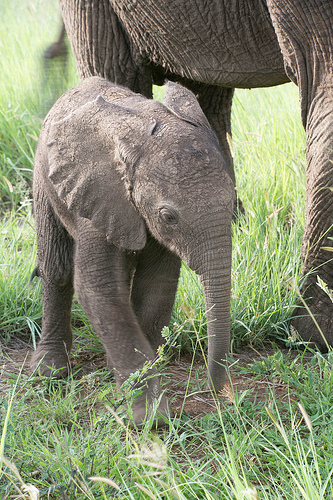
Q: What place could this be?
A: It is a field.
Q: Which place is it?
A: It is a field.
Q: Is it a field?
A: Yes, it is a field.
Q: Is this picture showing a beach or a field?
A: It is showing a field.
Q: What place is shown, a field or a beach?
A: It is a field.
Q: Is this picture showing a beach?
A: No, the picture is showing a field.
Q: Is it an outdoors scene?
A: Yes, it is outdoors.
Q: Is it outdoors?
A: Yes, it is outdoors.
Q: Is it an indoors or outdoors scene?
A: It is outdoors.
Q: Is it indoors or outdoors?
A: It is outdoors.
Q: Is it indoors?
A: No, it is outdoors.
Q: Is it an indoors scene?
A: No, it is outdoors.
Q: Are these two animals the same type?
A: Yes, all the animals are elephants.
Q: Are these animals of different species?
A: No, all the animals are elephants.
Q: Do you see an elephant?
A: Yes, there is an elephant.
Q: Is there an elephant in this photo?
A: Yes, there is an elephant.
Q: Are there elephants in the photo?
A: Yes, there is an elephant.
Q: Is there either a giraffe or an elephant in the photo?
A: Yes, there is an elephant.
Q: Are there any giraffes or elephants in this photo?
A: Yes, there is an elephant.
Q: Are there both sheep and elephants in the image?
A: No, there is an elephant but no sheep.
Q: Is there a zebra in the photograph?
A: No, there are no zebras.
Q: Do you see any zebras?
A: No, there are no zebras.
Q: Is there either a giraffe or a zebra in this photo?
A: No, there are no zebras or giraffes.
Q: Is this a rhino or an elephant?
A: This is an elephant.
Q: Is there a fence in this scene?
A: No, there are no fences.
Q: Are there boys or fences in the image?
A: No, there are no fences or boys.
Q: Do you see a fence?
A: No, there are no fences.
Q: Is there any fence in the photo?
A: No, there are no fences.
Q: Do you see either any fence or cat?
A: No, there are no fences or cats.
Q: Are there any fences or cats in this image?
A: No, there are no fences or cats.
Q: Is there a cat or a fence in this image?
A: No, there are no fences or cats.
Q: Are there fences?
A: No, there are no fences.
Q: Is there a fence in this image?
A: No, there are no fences.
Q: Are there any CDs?
A: No, there are no cds.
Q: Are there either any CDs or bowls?
A: No, there are no CDs or bowls.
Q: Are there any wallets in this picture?
A: No, there are no wallets.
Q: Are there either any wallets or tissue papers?
A: No, there are no wallets or tissue papers.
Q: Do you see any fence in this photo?
A: No, there are no fences.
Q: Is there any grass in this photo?
A: Yes, there is grass.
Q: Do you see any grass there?
A: Yes, there is grass.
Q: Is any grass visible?
A: Yes, there is grass.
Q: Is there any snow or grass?
A: Yes, there is grass.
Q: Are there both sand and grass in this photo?
A: No, there is grass but no sand.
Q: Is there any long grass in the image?
A: Yes, there is long grass.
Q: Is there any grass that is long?
A: Yes, there is grass that is long.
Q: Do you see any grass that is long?
A: Yes, there is grass that is long.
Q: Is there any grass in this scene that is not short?
A: Yes, there is long grass.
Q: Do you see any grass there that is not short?
A: Yes, there is long grass.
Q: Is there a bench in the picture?
A: No, there are no benches.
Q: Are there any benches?
A: No, there are no benches.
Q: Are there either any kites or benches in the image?
A: No, there are no benches or kites.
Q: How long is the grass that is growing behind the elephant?
A: The grass is long.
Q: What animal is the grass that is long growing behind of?
A: The grass is growing behind the elephant.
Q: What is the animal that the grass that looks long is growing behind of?
A: The animal is an elephant.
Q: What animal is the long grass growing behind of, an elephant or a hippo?
A: The grass is growing behind an elephant.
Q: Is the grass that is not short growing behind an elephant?
A: Yes, the grass is growing behind an elephant.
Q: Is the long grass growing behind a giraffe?
A: No, the grass is growing behind an elephant.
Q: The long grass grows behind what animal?
A: The grass grows behind the elephant.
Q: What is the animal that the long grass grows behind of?
A: The animal is an elephant.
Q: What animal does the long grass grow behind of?
A: The grass grows behind the elephant.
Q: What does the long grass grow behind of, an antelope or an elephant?
A: The grass grows behind an elephant.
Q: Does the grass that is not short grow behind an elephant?
A: Yes, the grass grows behind an elephant.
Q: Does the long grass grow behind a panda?
A: No, the grass grows behind an elephant.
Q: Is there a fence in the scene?
A: No, there are no fences.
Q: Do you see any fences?
A: No, there are no fences.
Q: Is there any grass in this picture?
A: Yes, there is grass.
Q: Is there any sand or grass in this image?
A: Yes, there is grass.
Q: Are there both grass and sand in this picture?
A: No, there is grass but no sand.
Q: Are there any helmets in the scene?
A: No, there are no helmets.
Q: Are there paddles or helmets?
A: No, there are no helmets or paddles.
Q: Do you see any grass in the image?
A: Yes, there is grass.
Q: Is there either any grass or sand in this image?
A: Yes, there is grass.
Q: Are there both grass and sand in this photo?
A: No, there is grass but no sand.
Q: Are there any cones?
A: No, there are no cones.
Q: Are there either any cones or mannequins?
A: No, there are no cones or mannequins.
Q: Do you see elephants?
A: Yes, there is an elephant.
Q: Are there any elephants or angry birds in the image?
A: Yes, there is an elephant.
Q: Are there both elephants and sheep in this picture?
A: No, there is an elephant but no sheep.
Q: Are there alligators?
A: No, there are no alligators.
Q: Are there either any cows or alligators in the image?
A: No, there are no alligators or cows.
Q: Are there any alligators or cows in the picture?
A: No, there are no alligators or cows.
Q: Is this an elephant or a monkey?
A: This is an elephant.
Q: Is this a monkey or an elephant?
A: This is an elephant.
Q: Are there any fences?
A: No, there are no fences.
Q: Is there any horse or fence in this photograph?
A: No, there are no fences or horses.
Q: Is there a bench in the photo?
A: No, there are no benches.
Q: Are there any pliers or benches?
A: No, there are no benches or pliers.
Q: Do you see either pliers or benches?
A: No, there are no benches or pliers.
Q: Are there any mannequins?
A: No, there are no mannequins.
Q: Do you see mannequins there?
A: No, there are no mannequins.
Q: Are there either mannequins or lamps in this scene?
A: No, there are no mannequins or lamps.